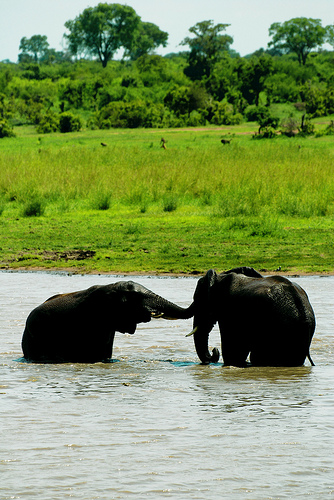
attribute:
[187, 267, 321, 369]
elephant — dark, playing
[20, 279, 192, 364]
elephant — dark, playing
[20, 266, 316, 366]
elephants — playing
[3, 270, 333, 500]
water — murky, here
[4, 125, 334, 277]
grass — green, here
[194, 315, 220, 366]
trunk — long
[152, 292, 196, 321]
trunk — extended, long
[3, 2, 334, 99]
trees — lush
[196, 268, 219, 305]
ear — big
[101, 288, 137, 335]
ear — big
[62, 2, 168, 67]
tree — tall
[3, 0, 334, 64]
sky — hazy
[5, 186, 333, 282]
brush — growing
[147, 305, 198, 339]
tusks — white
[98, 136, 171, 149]
gazelle — small, brown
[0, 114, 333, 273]
field — large